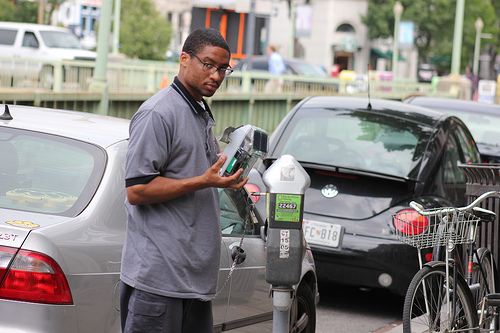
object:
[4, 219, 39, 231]
paw sticker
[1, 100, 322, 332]
car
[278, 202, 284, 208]
numbers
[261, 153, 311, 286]
parking meter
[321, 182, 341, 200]
logo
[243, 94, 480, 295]
car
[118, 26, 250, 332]
man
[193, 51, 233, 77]
glasses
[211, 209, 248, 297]
chain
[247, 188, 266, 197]
key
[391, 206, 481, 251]
basket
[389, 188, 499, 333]
bicycle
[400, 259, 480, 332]
tire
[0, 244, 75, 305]
taillight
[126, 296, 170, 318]
pocket flap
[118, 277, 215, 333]
pants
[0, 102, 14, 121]
antenna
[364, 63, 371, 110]
antenna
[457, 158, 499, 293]
trashcan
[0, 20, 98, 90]
van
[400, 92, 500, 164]
car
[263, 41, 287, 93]
man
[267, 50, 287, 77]
shirt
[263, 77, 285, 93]
pants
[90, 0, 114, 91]
lamp post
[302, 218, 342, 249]
license plate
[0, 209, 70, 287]
trunk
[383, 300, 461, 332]
sidewalk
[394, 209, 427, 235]
brake light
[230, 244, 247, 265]
handle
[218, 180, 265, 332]
door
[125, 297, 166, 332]
pocket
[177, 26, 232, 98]
head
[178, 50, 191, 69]
ear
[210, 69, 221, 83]
nose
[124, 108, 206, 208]
arm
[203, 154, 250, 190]
hand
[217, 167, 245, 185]
fingers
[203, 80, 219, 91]
mouth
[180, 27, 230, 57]
hair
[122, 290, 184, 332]
legs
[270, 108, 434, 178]
windows